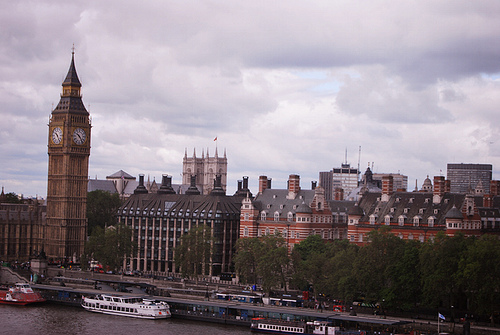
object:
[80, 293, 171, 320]
boat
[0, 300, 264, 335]
water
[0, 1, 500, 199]
sky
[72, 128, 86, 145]
clock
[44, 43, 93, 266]
tower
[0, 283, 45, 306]
boat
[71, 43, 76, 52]
vane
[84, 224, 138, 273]
tree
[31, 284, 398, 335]
bridge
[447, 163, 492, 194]
building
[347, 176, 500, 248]
buildings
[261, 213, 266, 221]
window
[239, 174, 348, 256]
building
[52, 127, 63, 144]
clock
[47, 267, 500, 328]
road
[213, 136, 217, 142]
flag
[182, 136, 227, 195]
building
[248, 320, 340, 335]
boat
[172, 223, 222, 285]
tree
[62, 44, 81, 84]
top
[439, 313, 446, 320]
flag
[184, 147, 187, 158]
poit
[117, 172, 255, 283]
building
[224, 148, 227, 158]
point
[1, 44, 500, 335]
city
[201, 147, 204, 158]
towers